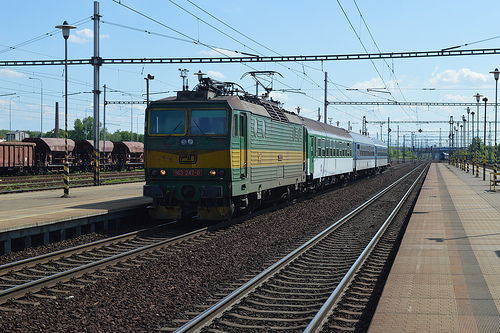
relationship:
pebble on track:
[341, 247, 346, 252] [164, 160, 431, 332]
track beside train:
[164, 160, 431, 332] [143, 80, 392, 223]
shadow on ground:
[424, 228, 499, 248] [366, 162, 499, 332]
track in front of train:
[1, 213, 235, 315] [143, 80, 392, 223]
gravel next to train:
[1, 140, 421, 330] [143, 80, 392, 223]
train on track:
[143, 80, 392, 223] [1, 213, 235, 315]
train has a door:
[143, 80, 392, 223] [238, 112, 249, 182]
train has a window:
[143, 80, 392, 223] [232, 114, 239, 138]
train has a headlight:
[143, 80, 392, 223] [148, 169, 170, 178]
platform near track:
[366, 162, 499, 332] [164, 160, 431, 332]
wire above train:
[327, 0, 432, 138] [143, 80, 392, 223]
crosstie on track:
[281, 269, 349, 279] [164, 160, 431, 332]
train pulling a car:
[143, 80, 392, 223] [304, 118, 355, 190]